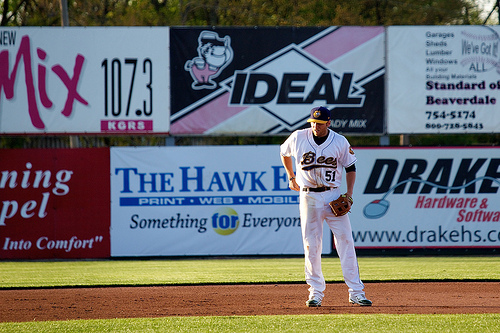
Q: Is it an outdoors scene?
A: Yes, it is outdoors.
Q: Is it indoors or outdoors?
A: It is outdoors.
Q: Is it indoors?
A: No, it is outdoors.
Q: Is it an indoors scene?
A: No, it is outdoors.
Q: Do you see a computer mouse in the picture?
A: Yes, there is a computer mouse.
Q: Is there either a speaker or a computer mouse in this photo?
A: Yes, there is a computer mouse.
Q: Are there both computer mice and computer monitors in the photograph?
A: No, there is a computer mouse but no computer monitors.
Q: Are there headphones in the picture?
A: No, there are no headphones.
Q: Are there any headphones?
A: No, there are no headphones.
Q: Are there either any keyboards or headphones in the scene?
A: No, there are no headphones or keyboards.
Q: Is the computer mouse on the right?
A: Yes, the computer mouse is on the right of the image.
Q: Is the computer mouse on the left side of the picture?
A: No, the computer mouse is on the right of the image.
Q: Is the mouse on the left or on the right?
A: The mouse is on the right of the image.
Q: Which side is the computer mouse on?
A: The computer mouse is on the right of the image.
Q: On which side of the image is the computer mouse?
A: The computer mouse is on the right of the image.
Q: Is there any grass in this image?
A: Yes, there is grass.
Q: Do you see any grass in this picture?
A: Yes, there is grass.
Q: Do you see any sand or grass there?
A: Yes, there is grass.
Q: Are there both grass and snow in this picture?
A: No, there is grass but no snow.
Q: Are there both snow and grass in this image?
A: No, there is grass but no snow.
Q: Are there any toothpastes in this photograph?
A: No, there are no toothpastes.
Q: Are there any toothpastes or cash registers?
A: No, there are no toothpastes or cash registers.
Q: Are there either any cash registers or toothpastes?
A: No, there are no toothpastes or cash registers.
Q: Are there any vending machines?
A: No, there are no vending machines.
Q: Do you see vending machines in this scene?
A: No, there are no vending machines.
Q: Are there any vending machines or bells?
A: No, there are no vending machines or bells.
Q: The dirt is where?
A: The dirt is on the field.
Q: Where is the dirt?
A: The dirt is on the field.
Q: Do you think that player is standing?
A: Yes, the player is standing.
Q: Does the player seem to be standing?
A: Yes, the player is standing.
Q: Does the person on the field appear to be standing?
A: Yes, the player is standing.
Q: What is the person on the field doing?
A: The player is standing.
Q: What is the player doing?
A: The player is standing.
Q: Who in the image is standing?
A: The player is standing.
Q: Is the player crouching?
A: No, the player is standing.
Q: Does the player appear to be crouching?
A: No, the player is standing.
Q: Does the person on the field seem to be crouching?
A: No, the player is standing.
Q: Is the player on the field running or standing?
A: The player is standing.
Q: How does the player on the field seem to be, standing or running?
A: The player is standing.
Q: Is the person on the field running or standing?
A: The player is standing.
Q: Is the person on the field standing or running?
A: The player is standing.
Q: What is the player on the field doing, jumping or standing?
A: The player is standing.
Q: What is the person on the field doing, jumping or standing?
A: The player is standing.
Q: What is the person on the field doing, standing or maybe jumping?
A: The player is standing.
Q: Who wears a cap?
A: The player wears a cap.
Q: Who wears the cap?
A: The player wears a cap.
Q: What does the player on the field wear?
A: The player wears a cap.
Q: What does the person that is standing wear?
A: The player wears a cap.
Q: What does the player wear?
A: The player wears a cap.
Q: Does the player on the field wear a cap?
A: Yes, the player wears a cap.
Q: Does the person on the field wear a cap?
A: Yes, the player wears a cap.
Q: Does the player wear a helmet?
A: No, the player wears a cap.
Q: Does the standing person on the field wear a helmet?
A: No, the player wears a cap.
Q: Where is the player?
A: The player is on the field.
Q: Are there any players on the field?
A: Yes, there is a player on the field.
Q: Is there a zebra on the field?
A: No, there is a player on the field.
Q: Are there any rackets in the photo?
A: No, there are no rackets.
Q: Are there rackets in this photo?
A: No, there are no rackets.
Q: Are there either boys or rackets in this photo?
A: No, there are no rackets or boys.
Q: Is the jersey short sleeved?
A: Yes, the jersey is short sleeved.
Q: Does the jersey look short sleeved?
A: Yes, the jersey is short sleeved.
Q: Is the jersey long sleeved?
A: No, the jersey is short sleeved.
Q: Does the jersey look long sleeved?
A: No, the jersey is short sleeved.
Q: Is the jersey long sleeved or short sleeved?
A: The jersey is short sleeved.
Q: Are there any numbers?
A: Yes, there are numbers.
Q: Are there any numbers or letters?
A: Yes, there are numbers.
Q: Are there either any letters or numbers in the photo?
A: Yes, there are numbers.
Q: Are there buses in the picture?
A: No, there are no buses.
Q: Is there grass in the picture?
A: Yes, there is grass.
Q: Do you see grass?
A: Yes, there is grass.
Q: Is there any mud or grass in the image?
A: Yes, there is grass.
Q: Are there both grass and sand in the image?
A: No, there is grass but no sand.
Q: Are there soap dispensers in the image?
A: No, there are no soap dispensers.